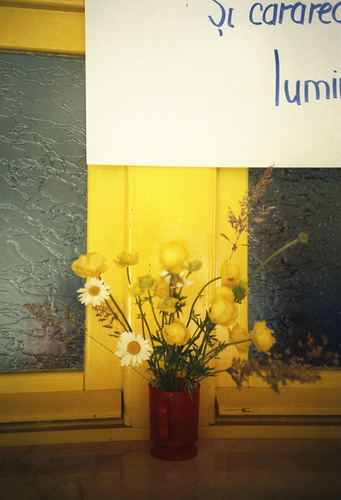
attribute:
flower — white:
[108, 321, 153, 373]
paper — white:
[84, 0, 340, 167]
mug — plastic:
[146, 371, 203, 459]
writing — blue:
[207, 1, 340, 109]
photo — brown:
[168, 40, 236, 111]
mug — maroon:
[140, 374, 212, 459]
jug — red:
[146, 379, 199, 459]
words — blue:
[207, 1, 340, 108]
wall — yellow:
[128, 169, 223, 230]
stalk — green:
[100, 277, 134, 333]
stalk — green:
[104, 299, 128, 332]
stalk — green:
[184, 276, 219, 326]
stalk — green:
[181, 317, 210, 354]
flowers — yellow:
[154, 229, 254, 341]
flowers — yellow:
[50, 240, 135, 278]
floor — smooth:
[0, 437, 340, 499]